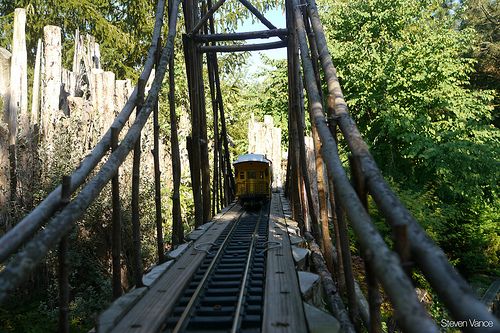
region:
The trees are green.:
[329, 3, 496, 151]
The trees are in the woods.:
[330, 6, 490, 178]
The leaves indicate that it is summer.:
[329, 4, 489, 231]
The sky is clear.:
[215, 4, 315, 68]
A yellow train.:
[206, 126, 292, 219]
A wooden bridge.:
[62, 5, 422, 328]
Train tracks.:
[150, 208, 292, 325]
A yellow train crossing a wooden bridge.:
[120, 4, 377, 326]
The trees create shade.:
[322, 99, 498, 298]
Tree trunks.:
[2, 21, 169, 185]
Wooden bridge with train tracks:
[1, 1, 499, 332]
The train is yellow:
[232, 149, 275, 214]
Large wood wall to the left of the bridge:
[2, 5, 185, 251]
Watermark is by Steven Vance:
[438, 316, 498, 331]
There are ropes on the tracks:
[184, 227, 284, 264]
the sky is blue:
[3, 1, 497, 116]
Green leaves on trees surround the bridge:
[1, 2, 499, 330]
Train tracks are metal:
[158, 177, 282, 330]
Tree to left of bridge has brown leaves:
[1, 113, 152, 331]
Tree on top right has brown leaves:
[458, 3, 499, 97]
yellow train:
[226, 148, 276, 208]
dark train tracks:
[130, 194, 305, 331]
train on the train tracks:
[221, 148, 288, 232]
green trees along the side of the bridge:
[262, 5, 494, 332]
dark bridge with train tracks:
[3, 2, 493, 332]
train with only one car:
[229, 147, 279, 204]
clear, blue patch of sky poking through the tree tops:
[219, 8, 291, 85]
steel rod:
[152, 112, 172, 261]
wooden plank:
[268, 198, 299, 332]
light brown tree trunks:
[8, 13, 62, 182]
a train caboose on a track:
[218, 136, 297, 223]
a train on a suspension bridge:
[6, 2, 489, 324]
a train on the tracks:
[89, 115, 367, 327]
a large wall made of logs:
[6, 5, 167, 176]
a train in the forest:
[4, 2, 487, 327]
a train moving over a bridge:
[10, 6, 489, 323]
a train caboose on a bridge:
[9, 2, 488, 327]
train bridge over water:
[3, 6, 490, 326]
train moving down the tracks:
[7, 5, 490, 324]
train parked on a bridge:
[6, 5, 489, 325]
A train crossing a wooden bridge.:
[116, 2, 416, 330]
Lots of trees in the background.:
[327, 5, 499, 243]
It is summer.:
[331, 5, 494, 243]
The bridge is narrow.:
[133, 1, 425, 331]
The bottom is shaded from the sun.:
[28, 123, 495, 318]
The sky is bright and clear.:
[221, 5, 309, 81]